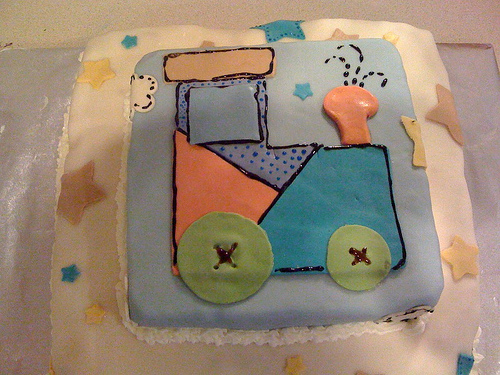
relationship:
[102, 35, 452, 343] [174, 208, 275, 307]
icing on wheel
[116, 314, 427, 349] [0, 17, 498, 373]
icing border around cake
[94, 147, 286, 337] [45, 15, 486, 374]
decoration on top of cake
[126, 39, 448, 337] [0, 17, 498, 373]
decoration on top of cake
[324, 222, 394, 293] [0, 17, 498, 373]
wheel on top of cake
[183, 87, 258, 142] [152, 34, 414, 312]
window on top of train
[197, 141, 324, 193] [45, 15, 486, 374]
dots on top of cake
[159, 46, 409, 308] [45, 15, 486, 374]
train drawn on top of cake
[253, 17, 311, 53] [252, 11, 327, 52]
sparkles on top of star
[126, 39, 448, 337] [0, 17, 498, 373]
decoration on cake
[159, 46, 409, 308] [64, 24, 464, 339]
train made icing